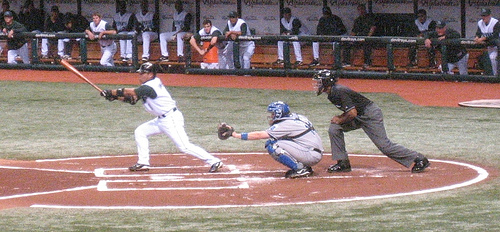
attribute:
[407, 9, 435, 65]
person — sitting., sitting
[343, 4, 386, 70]
person — sitting, sitting.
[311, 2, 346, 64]
person — sitting., sitting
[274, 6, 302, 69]
person — sitting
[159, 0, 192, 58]
person — sitting., sitting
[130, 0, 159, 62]
person — sitting., sitting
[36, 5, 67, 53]
person — sitting., sitting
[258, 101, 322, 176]
catcher — squatting.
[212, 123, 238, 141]
glove — raised., black., brown.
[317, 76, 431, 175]
umpire — dressed., watching., bent., crouching.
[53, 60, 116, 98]
bat — wooden., red., metal, brown.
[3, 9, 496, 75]
players — watching., sitting.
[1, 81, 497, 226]
grass — green, green.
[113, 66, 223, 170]
batter — swinging.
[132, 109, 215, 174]
pants — white.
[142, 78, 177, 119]
jersey — white.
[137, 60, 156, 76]
helmet — black.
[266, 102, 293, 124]
mask. — blue.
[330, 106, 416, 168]
pants — gray.